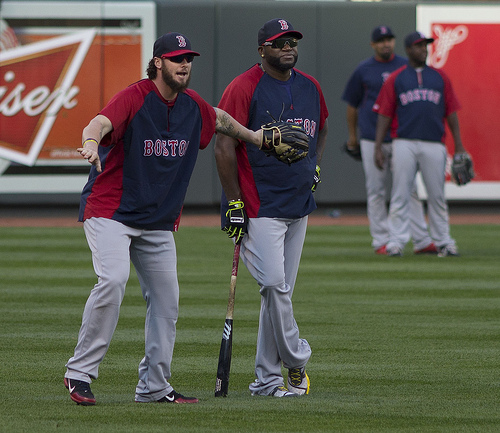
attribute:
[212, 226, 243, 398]
bat — black, red, brown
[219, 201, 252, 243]
gloves — black, yellow, green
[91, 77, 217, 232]
jersey — red, blue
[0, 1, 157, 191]
sign — orange, white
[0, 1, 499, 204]
wall — green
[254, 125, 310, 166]
mitt — black, yellow, brown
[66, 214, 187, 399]
pants — grey, gray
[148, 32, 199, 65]
baseball hat — blue, red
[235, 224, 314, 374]
legs — crossed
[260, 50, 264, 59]
earring — gold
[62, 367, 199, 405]
shoes — red, black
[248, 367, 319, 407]
sneakers — black, yellow